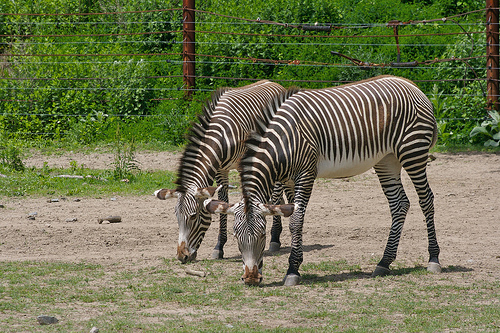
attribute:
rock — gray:
[36, 312, 63, 328]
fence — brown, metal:
[26, 27, 492, 179]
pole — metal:
[145, 27, 441, 108]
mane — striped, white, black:
[237, 85, 302, 211]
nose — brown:
[250, 274, 257, 281]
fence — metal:
[5, 16, 482, 121]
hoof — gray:
[280, 266, 303, 287]